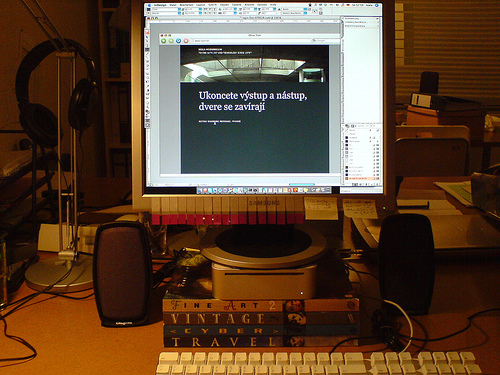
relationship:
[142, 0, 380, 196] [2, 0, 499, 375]
monitor on desk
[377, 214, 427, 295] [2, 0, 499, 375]
speakers on desk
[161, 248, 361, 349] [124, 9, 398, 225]
books under monitor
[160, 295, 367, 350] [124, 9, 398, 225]
books under monitor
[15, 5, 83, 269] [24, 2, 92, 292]
arm of lamp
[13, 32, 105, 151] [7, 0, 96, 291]
headphones hanging from lamp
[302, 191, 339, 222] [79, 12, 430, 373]
note on computer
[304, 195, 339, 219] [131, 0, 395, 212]
note on monitor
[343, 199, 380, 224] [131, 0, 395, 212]
note on monitor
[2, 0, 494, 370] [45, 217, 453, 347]
desk cluttered with items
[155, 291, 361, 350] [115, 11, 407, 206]
books under computer monitor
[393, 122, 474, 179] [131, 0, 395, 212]
folder organizer behind monitor